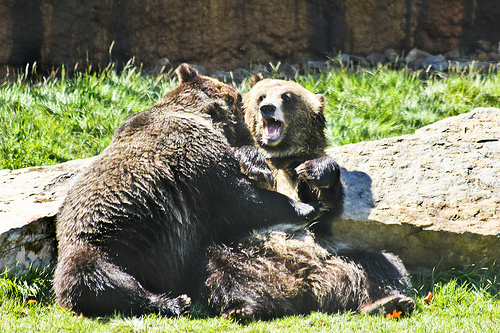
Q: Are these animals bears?
A: Yes, all the animals are bears.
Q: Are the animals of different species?
A: No, all the animals are bears.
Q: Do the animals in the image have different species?
A: No, all the animals are bears.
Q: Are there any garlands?
A: No, there are no garlands.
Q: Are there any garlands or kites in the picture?
A: No, there are no garlands or kites.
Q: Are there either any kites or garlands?
A: No, there are no garlands or kites.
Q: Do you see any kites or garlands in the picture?
A: No, there are no garlands or kites.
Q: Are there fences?
A: No, there are no fences.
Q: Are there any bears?
A: Yes, there is a bear.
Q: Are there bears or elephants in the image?
A: Yes, there is a bear.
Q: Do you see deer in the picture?
A: No, there are no deer.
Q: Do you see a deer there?
A: No, there is no deer.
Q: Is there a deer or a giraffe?
A: No, there are no deer or giraffes.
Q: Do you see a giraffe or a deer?
A: No, there are no deer or giraffes.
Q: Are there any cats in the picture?
A: No, there are no cats.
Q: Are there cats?
A: No, there are no cats.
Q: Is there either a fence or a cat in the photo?
A: No, there are no cats or fences.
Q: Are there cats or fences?
A: No, there are no cats or fences.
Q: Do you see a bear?
A: Yes, there is a bear.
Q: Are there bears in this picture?
A: Yes, there is a bear.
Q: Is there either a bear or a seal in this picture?
A: Yes, there is a bear.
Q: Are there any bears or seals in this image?
A: Yes, there is a bear.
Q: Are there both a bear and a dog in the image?
A: No, there is a bear but no dogs.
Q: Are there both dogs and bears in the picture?
A: No, there is a bear but no dogs.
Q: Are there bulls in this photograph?
A: No, there are no bulls.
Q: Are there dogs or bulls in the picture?
A: No, there are no bulls or dogs.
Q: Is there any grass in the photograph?
A: Yes, there is grass.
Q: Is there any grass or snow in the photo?
A: Yes, there is grass.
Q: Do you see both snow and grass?
A: No, there is grass but no snow.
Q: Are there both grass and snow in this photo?
A: No, there is grass but no snow.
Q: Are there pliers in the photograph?
A: No, there are no pliers.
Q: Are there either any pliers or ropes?
A: No, there are no pliers or ropes.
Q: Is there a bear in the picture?
A: Yes, there is a bear.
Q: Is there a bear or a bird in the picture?
A: Yes, there is a bear.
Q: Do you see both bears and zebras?
A: No, there is a bear but no zebras.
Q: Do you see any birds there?
A: No, there are no birds.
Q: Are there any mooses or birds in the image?
A: No, there are no birds or mooses.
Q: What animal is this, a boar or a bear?
A: This is a bear.